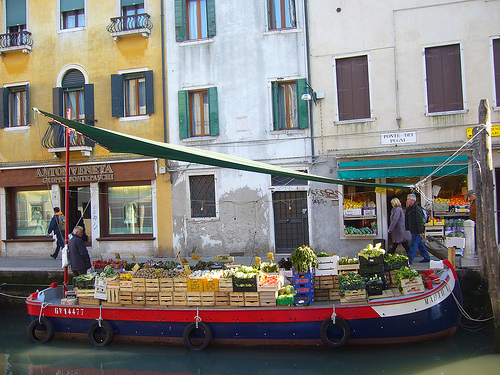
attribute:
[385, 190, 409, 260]
person — walking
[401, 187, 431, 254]
person — walking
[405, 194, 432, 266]
man — grey-haired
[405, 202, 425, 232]
jacket — green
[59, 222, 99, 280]
man — standing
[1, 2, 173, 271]
building — tall, yellow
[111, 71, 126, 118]
shutter — black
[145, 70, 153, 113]
shutter — black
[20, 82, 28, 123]
shutter — black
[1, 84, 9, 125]
shutter — black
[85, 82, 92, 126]
shutter — black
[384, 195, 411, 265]
woman — blonde-haired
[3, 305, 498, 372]
river — red, white, blue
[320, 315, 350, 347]
tire — black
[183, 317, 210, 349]
tire — black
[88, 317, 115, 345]
tire — black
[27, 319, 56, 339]
tire — black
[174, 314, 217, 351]
tire — black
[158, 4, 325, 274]
building — tall, gray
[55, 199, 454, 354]
boat — full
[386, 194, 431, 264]
couple — walking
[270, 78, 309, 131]
shutter — green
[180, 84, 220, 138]
shutter — green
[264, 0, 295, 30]
shutter — green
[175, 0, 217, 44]
shutter — green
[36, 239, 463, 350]
boat — painted